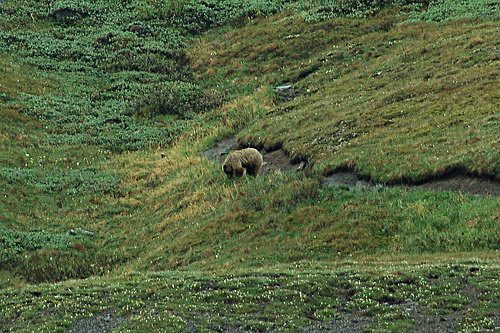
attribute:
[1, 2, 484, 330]
field — grassy, green, large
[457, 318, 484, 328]
flowers — small, white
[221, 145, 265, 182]
bear — brown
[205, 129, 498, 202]
dirt path — brown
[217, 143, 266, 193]
bear — brown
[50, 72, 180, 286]
grass — yellow, green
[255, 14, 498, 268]
hill — grassy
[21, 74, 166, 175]
grass — green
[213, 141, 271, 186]
bear — brown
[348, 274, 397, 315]
flowers — white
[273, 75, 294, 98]
rock — gray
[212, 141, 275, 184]
bear — hunting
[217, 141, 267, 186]
bear — bending forwards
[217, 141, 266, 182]
bear — small, brown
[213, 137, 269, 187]
bear — brown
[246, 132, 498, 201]
patch — long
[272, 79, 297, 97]
something — white